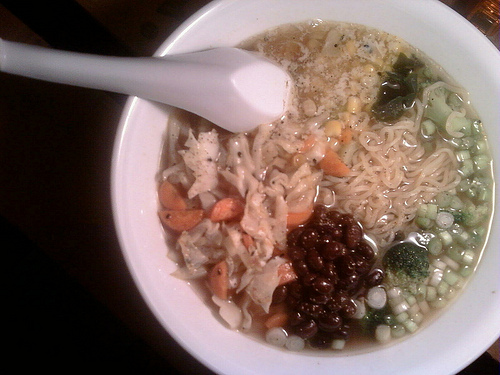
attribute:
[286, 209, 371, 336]
beans — in a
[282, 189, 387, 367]
food — piece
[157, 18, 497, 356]
soup — white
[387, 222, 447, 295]
broccoli — cooked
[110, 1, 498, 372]
bowl — soup, has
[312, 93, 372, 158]
kernels — corn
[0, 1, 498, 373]
table — under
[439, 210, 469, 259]
onions — Sliced green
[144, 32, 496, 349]
food — light, Asian